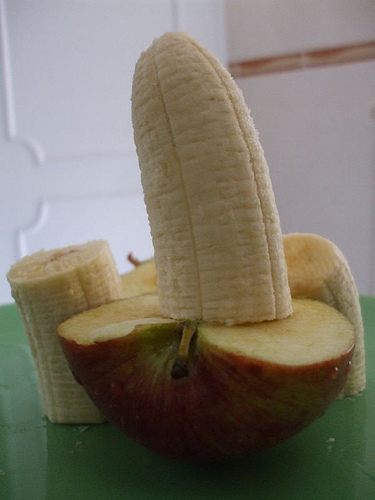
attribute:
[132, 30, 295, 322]
piece — banana, pointing, pointing up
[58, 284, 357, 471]
apple — half, cut, cut in half, red, sliced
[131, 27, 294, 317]
banana — stacked, half, standing, light yellow, cut, cut in half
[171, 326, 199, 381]
stem — brown, apple's, yellow, here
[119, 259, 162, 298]
apple — halve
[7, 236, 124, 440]
piece — banana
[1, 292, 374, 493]
counter top — shiny, green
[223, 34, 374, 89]
decoration — red, yellow, wall decoration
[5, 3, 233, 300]
wall — white, paneled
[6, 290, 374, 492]
counter — green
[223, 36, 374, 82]
sign — orange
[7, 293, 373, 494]
table — green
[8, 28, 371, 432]
bananas — peeled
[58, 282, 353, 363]
flesh — apple's, white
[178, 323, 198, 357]
ring — green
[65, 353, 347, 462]
skin — apple's, red, green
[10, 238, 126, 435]
section — banana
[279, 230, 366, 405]
section — banana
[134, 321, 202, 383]
color — green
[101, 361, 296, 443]
coloring — brown